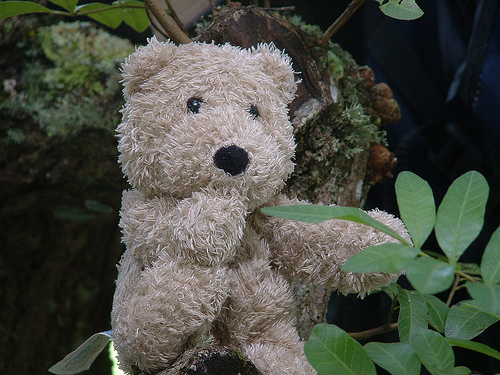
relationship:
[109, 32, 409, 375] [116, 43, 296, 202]
animal has face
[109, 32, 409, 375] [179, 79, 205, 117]
animal has eye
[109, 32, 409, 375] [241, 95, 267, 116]
animal has eye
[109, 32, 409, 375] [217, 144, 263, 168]
animal has nose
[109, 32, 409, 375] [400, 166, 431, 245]
animal near leaf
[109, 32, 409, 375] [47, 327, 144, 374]
animal has tag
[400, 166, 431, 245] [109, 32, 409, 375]
leaf in front of animal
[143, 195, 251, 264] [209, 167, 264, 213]
arm near mouth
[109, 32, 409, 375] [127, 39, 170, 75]
animal has ear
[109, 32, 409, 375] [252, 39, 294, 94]
animal has ear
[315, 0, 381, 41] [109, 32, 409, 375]
stick behind animal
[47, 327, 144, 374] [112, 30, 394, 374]
tag on animal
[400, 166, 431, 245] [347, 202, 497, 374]
leaf from house plant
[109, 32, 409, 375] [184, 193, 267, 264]
animal has paw